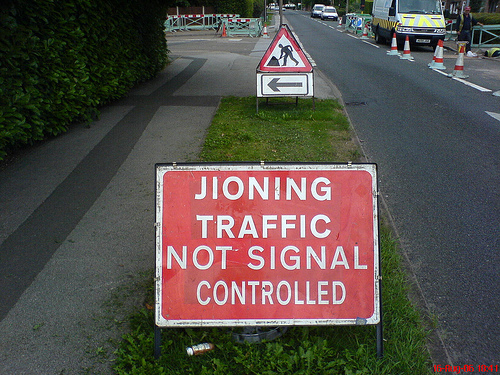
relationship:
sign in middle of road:
[155, 161, 374, 329] [33, 6, 483, 357]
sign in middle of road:
[253, 23, 320, 100] [33, 6, 483, 357]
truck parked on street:
[366, 0, 448, 47] [273, 3, 498, 372]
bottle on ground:
[185, 340, 217, 358] [386, 73, 454, 174]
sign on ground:
[248, 26, 328, 118] [58, 34, 484, 373]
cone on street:
[401, 35, 415, 60] [272, 8, 484, 358]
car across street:
[319, 3, 339, 22] [272, 8, 484, 358]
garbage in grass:
[185, 340, 217, 357] [106, 95, 437, 374]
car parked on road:
[318, 4, 338, 22] [278, 0, 498, 372]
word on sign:
[194, 174, 330, 200] [155, 161, 374, 329]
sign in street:
[155, 161, 374, 329] [158, 12, 499, 357]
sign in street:
[155, 147, 373, 329] [0, 10, 498, 373]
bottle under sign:
[185, 340, 222, 360] [155, 161, 374, 329]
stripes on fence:
[225, 14, 253, 24] [168, 11, 240, 28]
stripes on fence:
[164, 12, 240, 21] [168, 11, 240, 28]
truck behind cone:
[366, 0, 448, 47] [387, 32, 400, 56]